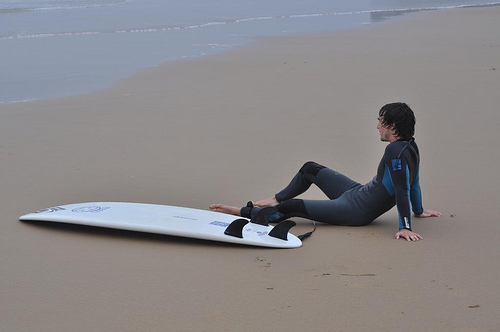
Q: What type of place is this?
A: It is a beach.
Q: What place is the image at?
A: It is at the beach.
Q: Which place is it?
A: It is a beach.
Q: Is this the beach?
A: Yes, it is the beach.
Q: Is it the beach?
A: Yes, it is the beach.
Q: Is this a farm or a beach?
A: It is a beach.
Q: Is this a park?
A: No, it is a beach.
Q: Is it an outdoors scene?
A: Yes, it is outdoors.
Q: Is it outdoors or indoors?
A: It is outdoors.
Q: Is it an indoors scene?
A: No, it is outdoors.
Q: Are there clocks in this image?
A: No, there are no clocks.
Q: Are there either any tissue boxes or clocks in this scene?
A: No, there are no clocks or tissue boxes.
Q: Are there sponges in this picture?
A: No, there are no sponges.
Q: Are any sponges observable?
A: No, there are no sponges.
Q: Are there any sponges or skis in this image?
A: No, there are no sponges or skis.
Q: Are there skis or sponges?
A: No, there are no sponges or skis.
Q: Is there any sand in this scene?
A: Yes, there is sand.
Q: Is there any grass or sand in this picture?
A: Yes, there is sand.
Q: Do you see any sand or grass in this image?
A: Yes, there is sand.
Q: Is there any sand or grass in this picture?
A: Yes, there is sand.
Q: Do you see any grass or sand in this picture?
A: Yes, there is sand.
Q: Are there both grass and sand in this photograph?
A: No, there is sand but no grass.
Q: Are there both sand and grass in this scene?
A: No, there is sand but no grass.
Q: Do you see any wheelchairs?
A: No, there are no wheelchairs.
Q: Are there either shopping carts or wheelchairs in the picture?
A: No, there are no wheelchairs or shopping carts.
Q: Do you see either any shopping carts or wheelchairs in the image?
A: No, there are no wheelchairs or shopping carts.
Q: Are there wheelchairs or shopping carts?
A: No, there are no wheelchairs or shopping carts.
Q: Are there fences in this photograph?
A: No, there are no fences.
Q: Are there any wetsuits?
A: Yes, there is a wetsuit.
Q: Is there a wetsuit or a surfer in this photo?
A: Yes, there is a wetsuit.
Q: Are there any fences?
A: No, there are no fences.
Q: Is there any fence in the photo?
A: No, there are no fences.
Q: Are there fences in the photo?
A: No, there are no fences.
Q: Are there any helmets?
A: No, there are no helmets.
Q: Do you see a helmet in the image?
A: No, there are no helmets.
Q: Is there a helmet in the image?
A: No, there are no helmets.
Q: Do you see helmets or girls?
A: No, there are no helmets or girls.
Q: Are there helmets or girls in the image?
A: No, there are no helmets or girls.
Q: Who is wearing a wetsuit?
A: The man is wearing a wetsuit.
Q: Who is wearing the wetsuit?
A: The man is wearing a wetsuit.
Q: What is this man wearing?
A: The man is wearing a wetsuit.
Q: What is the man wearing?
A: The man is wearing a wetsuit.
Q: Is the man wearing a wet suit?
A: Yes, the man is wearing a wet suit.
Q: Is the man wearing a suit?
A: No, the man is wearing a wet suit.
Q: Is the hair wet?
A: Yes, the hair is wet.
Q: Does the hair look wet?
A: Yes, the hair is wet.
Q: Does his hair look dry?
A: No, the hair is wet.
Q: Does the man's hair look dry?
A: No, the hair is wet.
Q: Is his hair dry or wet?
A: The hair is wet.